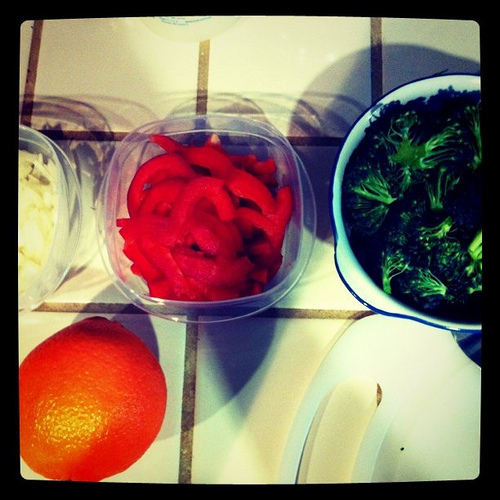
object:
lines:
[1, 14, 387, 489]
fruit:
[18, 317, 168, 484]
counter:
[17, 16, 480, 482]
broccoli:
[345, 83, 481, 311]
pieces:
[114, 133, 292, 302]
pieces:
[17, 147, 56, 287]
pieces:
[344, 87, 481, 312]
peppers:
[119, 133, 291, 295]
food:
[116, 137, 293, 302]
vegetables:
[1, 85, 483, 320]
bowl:
[331, 72, 494, 333]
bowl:
[99, 95, 309, 327]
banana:
[294, 376, 384, 493]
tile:
[179, 41, 380, 149]